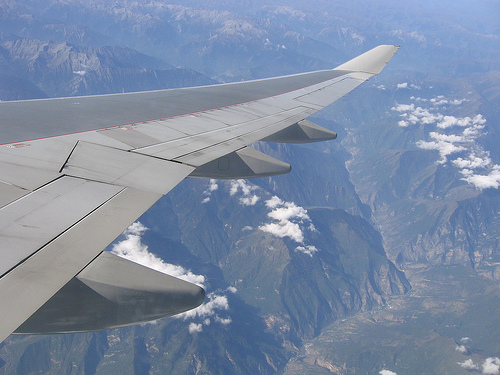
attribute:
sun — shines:
[17, 25, 115, 81]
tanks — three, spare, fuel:
[27, 105, 357, 355]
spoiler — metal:
[52, 135, 199, 205]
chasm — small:
[334, 135, 419, 294]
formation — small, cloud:
[391, 86, 497, 209]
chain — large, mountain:
[8, 5, 498, 373]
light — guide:
[8, 132, 38, 158]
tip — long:
[331, 32, 401, 97]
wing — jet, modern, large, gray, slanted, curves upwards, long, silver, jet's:
[2, 42, 408, 361]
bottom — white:
[47, 123, 364, 348]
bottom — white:
[194, 146, 315, 190]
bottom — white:
[270, 115, 337, 145]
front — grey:
[1, 77, 147, 146]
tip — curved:
[339, 30, 414, 94]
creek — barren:
[283, 118, 413, 368]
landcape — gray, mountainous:
[3, 0, 498, 373]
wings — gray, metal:
[0, 43, 397, 346]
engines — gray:
[192, 120, 338, 176]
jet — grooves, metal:
[0, 41, 397, 343]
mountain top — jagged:
[3, 39, 214, 89]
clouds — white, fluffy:
[112, 79, 498, 330]